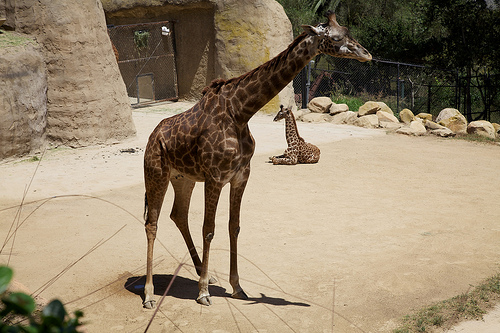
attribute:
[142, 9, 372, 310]
giraffe — looking around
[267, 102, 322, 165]
giraffe — looking around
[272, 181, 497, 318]
ground —  cement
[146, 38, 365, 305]
giraffe — looking around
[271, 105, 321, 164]
giraffe — sitting, looking around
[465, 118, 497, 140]
rock —  lined up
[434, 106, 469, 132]
rock —  lined up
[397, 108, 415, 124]
rock —  lined up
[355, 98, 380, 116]
rock —  lined up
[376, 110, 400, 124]
rock —  lined up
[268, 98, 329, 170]
giraffe — sitting